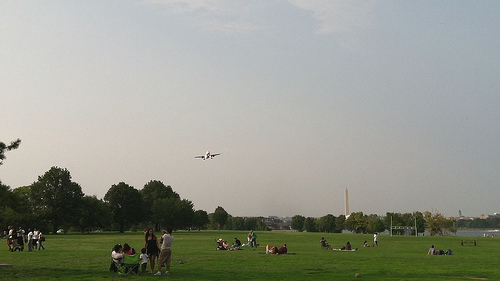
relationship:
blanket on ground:
[329, 247, 356, 252] [0, 231, 495, 279]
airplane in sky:
[192, 150, 222, 161] [3, 2, 495, 214]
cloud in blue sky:
[0, 0, 499, 219] [32, 22, 221, 115]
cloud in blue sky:
[0, 0, 499, 219] [3, 47, 498, 142]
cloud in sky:
[0, 0, 499, 219] [3, 2, 495, 214]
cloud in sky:
[0, 0, 499, 219] [207, 37, 407, 119]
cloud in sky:
[165, 2, 362, 37] [201, 32, 375, 124]